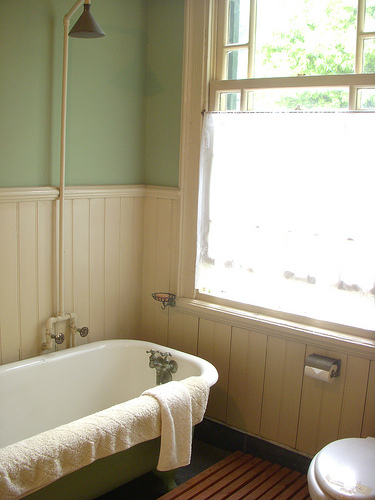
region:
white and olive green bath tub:
[0, 334, 225, 495]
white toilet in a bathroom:
[304, 428, 369, 491]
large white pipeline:
[53, 1, 68, 349]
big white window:
[193, 9, 373, 335]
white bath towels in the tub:
[0, 370, 220, 496]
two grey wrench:
[49, 321, 85, 347]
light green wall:
[0, 0, 186, 183]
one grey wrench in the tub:
[150, 347, 173, 382]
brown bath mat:
[154, 452, 310, 497]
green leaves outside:
[263, 12, 374, 109]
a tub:
[91, 296, 171, 427]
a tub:
[106, 361, 220, 491]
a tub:
[81, 353, 172, 492]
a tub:
[98, 338, 201, 451]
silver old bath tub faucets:
[115, 344, 174, 390]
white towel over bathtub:
[88, 368, 218, 495]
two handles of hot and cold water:
[17, 322, 95, 370]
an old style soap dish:
[136, 283, 183, 328]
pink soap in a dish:
[152, 285, 179, 320]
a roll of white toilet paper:
[271, 350, 355, 410]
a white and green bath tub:
[10, 330, 214, 497]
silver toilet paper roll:
[286, 351, 342, 397]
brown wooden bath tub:
[215, 453, 298, 495]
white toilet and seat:
[295, 417, 364, 488]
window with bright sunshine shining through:
[198, 106, 370, 329]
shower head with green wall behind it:
[21, 2, 110, 156]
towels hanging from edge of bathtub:
[106, 326, 235, 439]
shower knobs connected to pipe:
[42, 301, 98, 343]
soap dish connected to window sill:
[138, 262, 183, 311]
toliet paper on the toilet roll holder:
[299, 351, 355, 396]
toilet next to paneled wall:
[301, 413, 373, 498]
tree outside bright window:
[234, 8, 366, 100]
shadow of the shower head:
[108, 14, 164, 129]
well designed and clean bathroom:
[29, 35, 373, 489]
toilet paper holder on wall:
[280, 337, 357, 402]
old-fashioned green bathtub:
[2, 338, 233, 497]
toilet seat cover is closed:
[267, 420, 372, 498]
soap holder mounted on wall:
[110, 268, 201, 334]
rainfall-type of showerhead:
[23, 7, 154, 251]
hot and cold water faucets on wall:
[13, 280, 108, 366]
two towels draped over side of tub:
[9, 370, 220, 498]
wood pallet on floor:
[131, 438, 294, 498]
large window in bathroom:
[142, 91, 372, 367]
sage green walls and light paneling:
[4, 2, 196, 343]